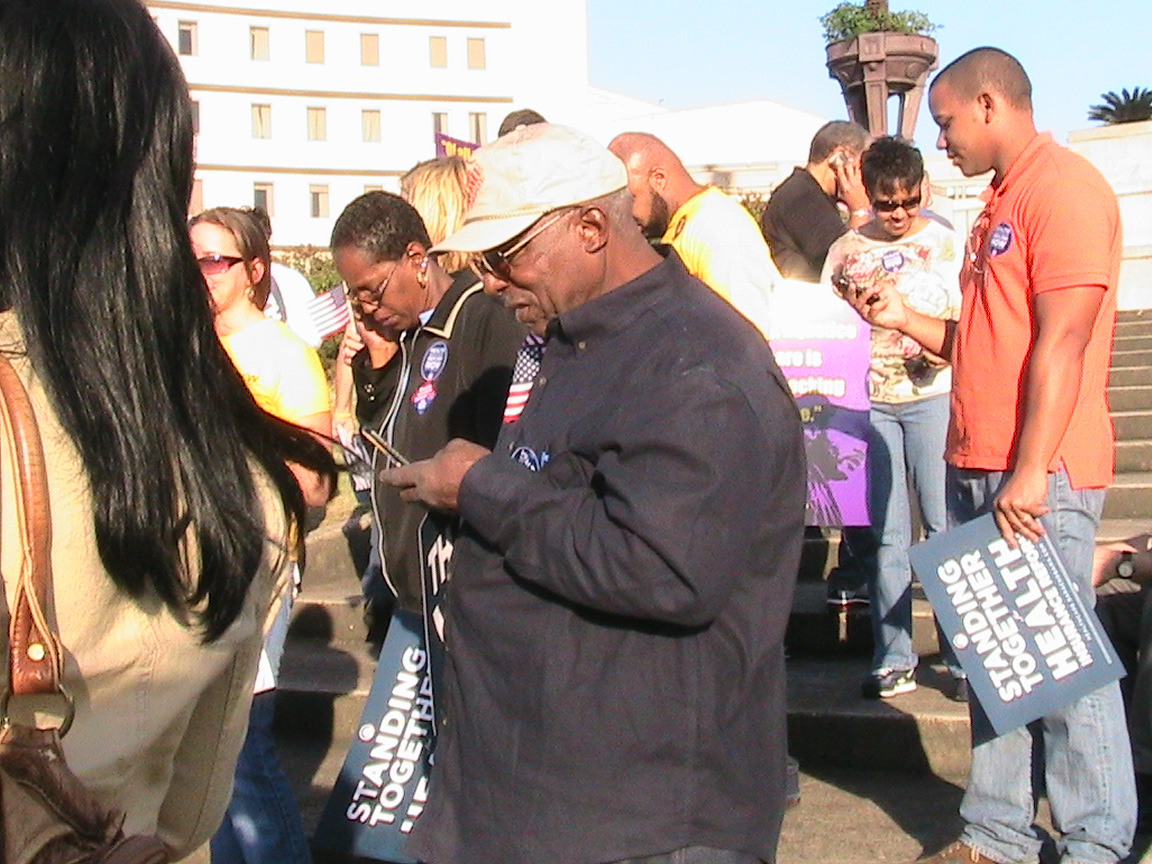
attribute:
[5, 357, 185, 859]
bag — brown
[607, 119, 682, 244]
head — bald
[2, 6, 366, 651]
hair — black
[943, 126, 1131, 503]
shirt — red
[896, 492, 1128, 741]
sign — blue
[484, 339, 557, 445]
flag — American